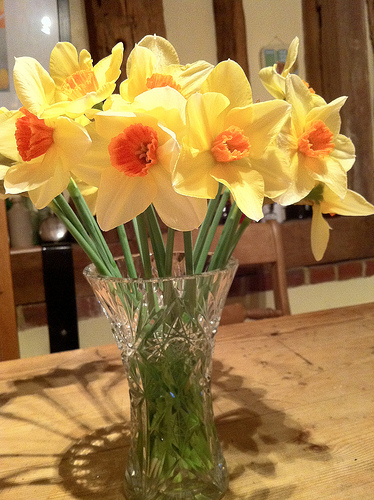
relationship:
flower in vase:
[84, 65, 224, 220] [43, 246, 269, 499]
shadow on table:
[30, 327, 140, 491] [6, 333, 371, 446]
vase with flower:
[43, 246, 269, 499] [84, 65, 224, 220]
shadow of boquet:
[30, 327, 140, 491] [13, 39, 356, 264]